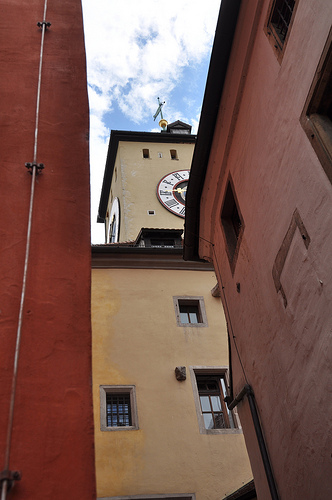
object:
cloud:
[82, 1, 233, 248]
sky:
[83, 1, 219, 248]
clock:
[154, 166, 193, 218]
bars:
[107, 394, 131, 425]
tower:
[96, 130, 197, 247]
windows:
[104, 387, 133, 429]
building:
[91, 263, 257, 500]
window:
[271, 207, 311, 308]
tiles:
[92, 241, 184, 249]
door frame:
[298, 25, 332, 188]